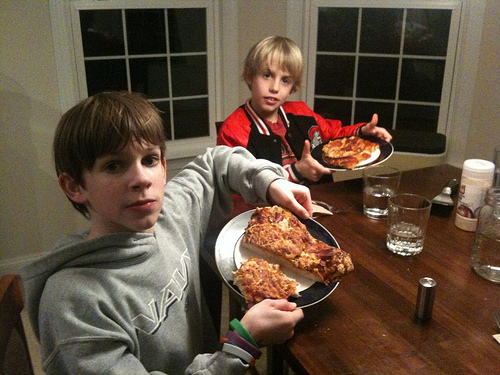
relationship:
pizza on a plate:
[321, 136, 381, 167] [310, 135, 393, 173]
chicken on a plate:
[233, 255, 299, 310] [215, 204, 343, 312]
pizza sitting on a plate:
[321, 136, 381, 167] [310, 135, 393, 173]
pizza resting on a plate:
[321, 136, 381, 167] [310, 135, 393, 173]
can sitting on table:
[453, 157, 495, 233] [190, 162, 496, 375]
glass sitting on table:
[386, 192, 432, 259] [190, 162, 496, 375]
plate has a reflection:
[215, 204, 343, 312] [216, 224, 249, 271]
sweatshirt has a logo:
[19, 144, 289, 375] [128, 246, 194, 335]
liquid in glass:
[391, 223, 422, 244] [386, 192, 432, 259]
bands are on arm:
[219, 319, 261, 366] [36, 264, 255, 374]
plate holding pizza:
[310, 135, 393, 173] [321, 136, 381, 167]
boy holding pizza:
[215, 35, 390, 217] [321, 136, 381, 167]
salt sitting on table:
[414, 274, 436, 323] [190, 162, 496, 375]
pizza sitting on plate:
[321, 136, 381, 167] [310, 135, 393, 173]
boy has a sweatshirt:
[41, 88, 313, 375] [19, 144, 289, 375]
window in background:
[62, 3, 227, 161] [3, 0, 499, 188]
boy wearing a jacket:
[215, 35, 390, 217] [218, 96, 364, 208]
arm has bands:
[36, 264, 255, 374] [221, 317, 263, 365]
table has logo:
[190, 162, 496, 375] [131, 246, 192, 336]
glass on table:
[386, 192, 432, 259] [190, 162, 496, 375]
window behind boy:
[62, 3, 227, 161] [41, 88, 313, 375]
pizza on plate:
[321, 136, 381, 167] [310, 135, 393, 173]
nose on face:
[128, 156, 152, 192] [89, 125, 164, 231]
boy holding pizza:
[41, 88, 313, 375] [233, 204, 354, 308]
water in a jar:
[474, 231, 499, 280] [469, 187, 498, 284]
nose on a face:
[268, 74, 283, 93] [253, 62, 292, 113]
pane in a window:
[167, 7, 209, 57] [62, 3, 227, 161]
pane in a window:
[125, 5, 167, 54] [62, 3, 227, 161]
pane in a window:
[79, 5, 125, 59] [62, 3, 227, 161]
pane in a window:
[85, 56, 129, 98] [62, 3, 227, 161]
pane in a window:
[168, 55, 210, 97] [62, 3, 227, 161]